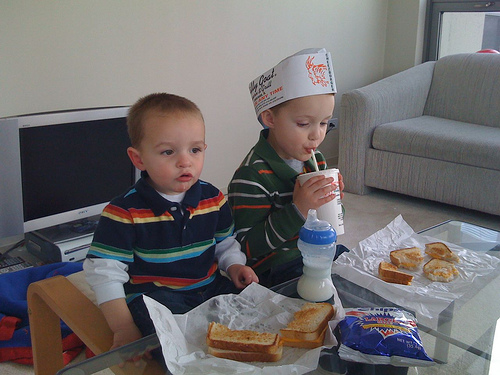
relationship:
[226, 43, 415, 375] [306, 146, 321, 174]
child drinking from straw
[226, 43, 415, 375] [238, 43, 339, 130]
child wearing a paper hat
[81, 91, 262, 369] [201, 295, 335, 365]
child eating a meal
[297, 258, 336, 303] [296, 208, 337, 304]
milk in sippy cup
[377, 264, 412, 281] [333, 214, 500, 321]
cheese in wrapper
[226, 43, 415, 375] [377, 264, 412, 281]
child eating cheese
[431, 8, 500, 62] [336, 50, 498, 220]
window in back of edge of chair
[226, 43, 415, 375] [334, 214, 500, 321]
child eating lunch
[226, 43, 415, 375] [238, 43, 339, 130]
child wearing paper hat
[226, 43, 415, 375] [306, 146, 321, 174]
child drinking through straw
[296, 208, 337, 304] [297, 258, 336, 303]
sippy cup filled with milk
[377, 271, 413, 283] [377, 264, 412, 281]
cheese on cheese